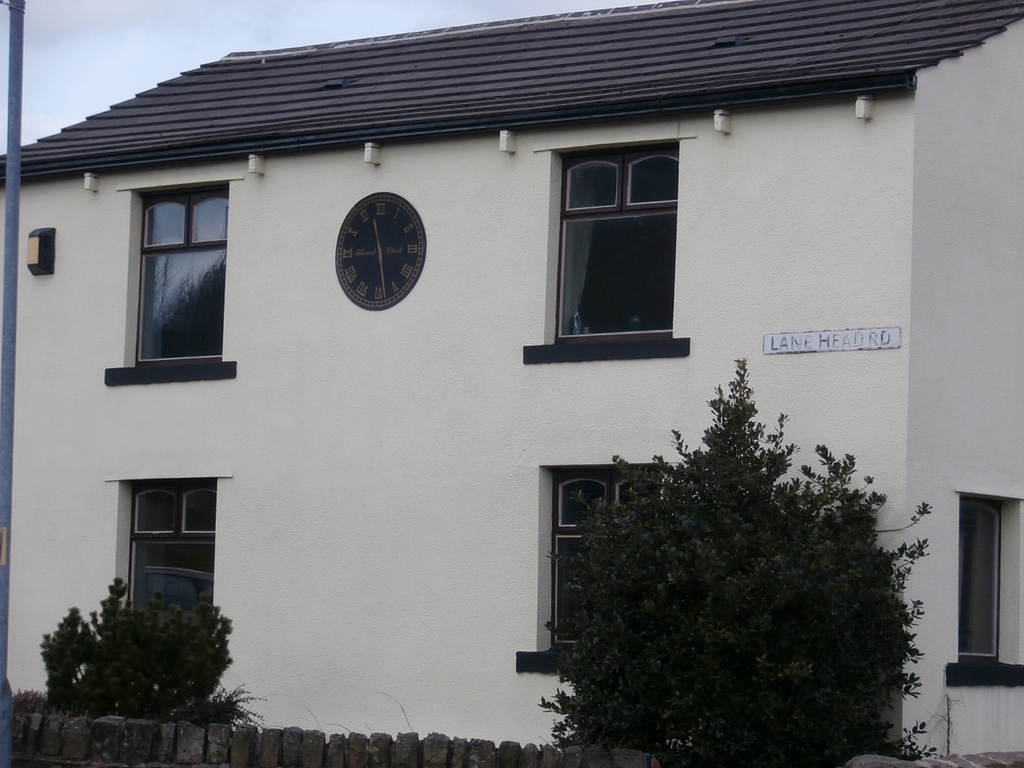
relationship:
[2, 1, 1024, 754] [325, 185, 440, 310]
building has clock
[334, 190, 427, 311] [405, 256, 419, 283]
clock with numeral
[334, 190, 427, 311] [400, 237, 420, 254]
clock with numeral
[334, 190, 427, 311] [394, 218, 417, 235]
clock with numeral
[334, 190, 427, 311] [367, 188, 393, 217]
clock with numeral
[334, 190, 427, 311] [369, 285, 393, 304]
clock with numeral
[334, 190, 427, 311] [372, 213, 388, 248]
clock with hand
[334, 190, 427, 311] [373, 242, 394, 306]
clock with hand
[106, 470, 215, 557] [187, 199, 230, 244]
window beneath plate glass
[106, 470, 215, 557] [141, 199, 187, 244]
window beneath plate glass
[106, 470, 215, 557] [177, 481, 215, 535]
window beneath plate glass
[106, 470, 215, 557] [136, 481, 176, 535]
window beneath plate glass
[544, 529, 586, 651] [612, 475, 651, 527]
window beneath plate glass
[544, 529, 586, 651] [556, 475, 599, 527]
window beneath plate glass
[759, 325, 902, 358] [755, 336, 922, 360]
letters with letters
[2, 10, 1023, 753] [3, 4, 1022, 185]
building with roof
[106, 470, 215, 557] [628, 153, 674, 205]
window beneath plate glass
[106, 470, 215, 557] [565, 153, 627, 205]
window beneath plate glass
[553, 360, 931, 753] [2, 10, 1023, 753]
bush beside building